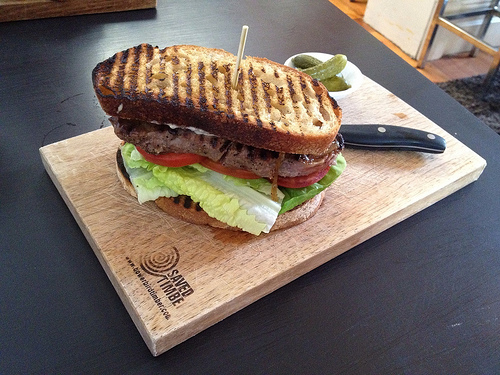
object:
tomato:
[280, 171, 322, 184]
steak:
[110, 122, 320, 174]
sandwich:
[88, 43, 348, 236]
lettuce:
[122, 145, 281, 235]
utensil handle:
[339, 125, 445, 156]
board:
[92, 42, 339, 230]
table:
[2, 4, 496, 373]